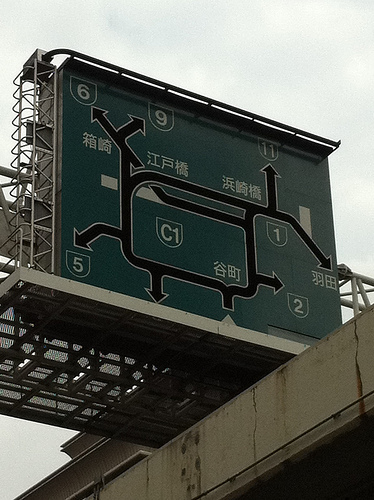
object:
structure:
[0, 50, 368, 447]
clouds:
[324, 1, 372, 39]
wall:
[208, 400, 302, 451]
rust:
[358, 402, 365, 419]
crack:
[345, 318, 369, 425]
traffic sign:
[65, 73, 341, 320]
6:
[77, 84, 90, 100]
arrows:
[90, 106, 109, 124]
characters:
[66, 72, 340, 319]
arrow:
[144, 287, 169, 303]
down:
[144, 278, 170, 305]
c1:
[160, 224, 178, 244]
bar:
[51, 46, 341, 156]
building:
[11, 419, 143, 499]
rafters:
[8, 58, 56, 278]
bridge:
[81, 313, 374, 499]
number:
[293, 298, 303, 314]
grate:
[0, 278, 258, 428]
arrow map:
[72, 104, 334, 311]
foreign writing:
[77, 129, 336, 292]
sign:
[41, 38, 358, 345]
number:
[73, 257, 84, 273]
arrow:
[260, 163, 283, 179]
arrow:
[272, 270, 285, 295]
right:
[268, 271, 285, 297]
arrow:
[73, 227, 93, 252]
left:
[73, 226, 97, 254]